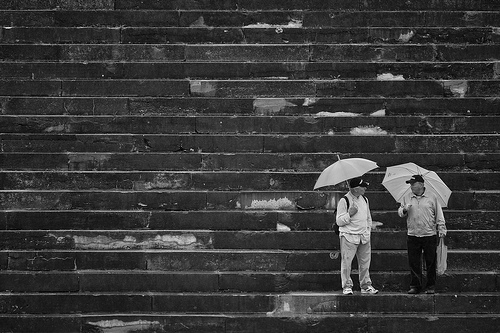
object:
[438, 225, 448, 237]
hand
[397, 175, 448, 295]
man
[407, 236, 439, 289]
pants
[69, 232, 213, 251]
worn step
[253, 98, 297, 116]
worn step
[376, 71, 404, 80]
worn step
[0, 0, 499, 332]
steps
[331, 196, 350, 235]
backpack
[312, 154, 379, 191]
umbrella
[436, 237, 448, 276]
bag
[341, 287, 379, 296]
shoes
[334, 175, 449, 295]
two men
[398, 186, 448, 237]
jacket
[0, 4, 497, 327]
staircase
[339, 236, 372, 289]
jeans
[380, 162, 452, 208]
man's umbrella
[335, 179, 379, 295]
man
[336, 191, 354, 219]
shoulder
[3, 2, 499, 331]
wall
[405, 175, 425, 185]
ball cap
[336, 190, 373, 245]
shirt